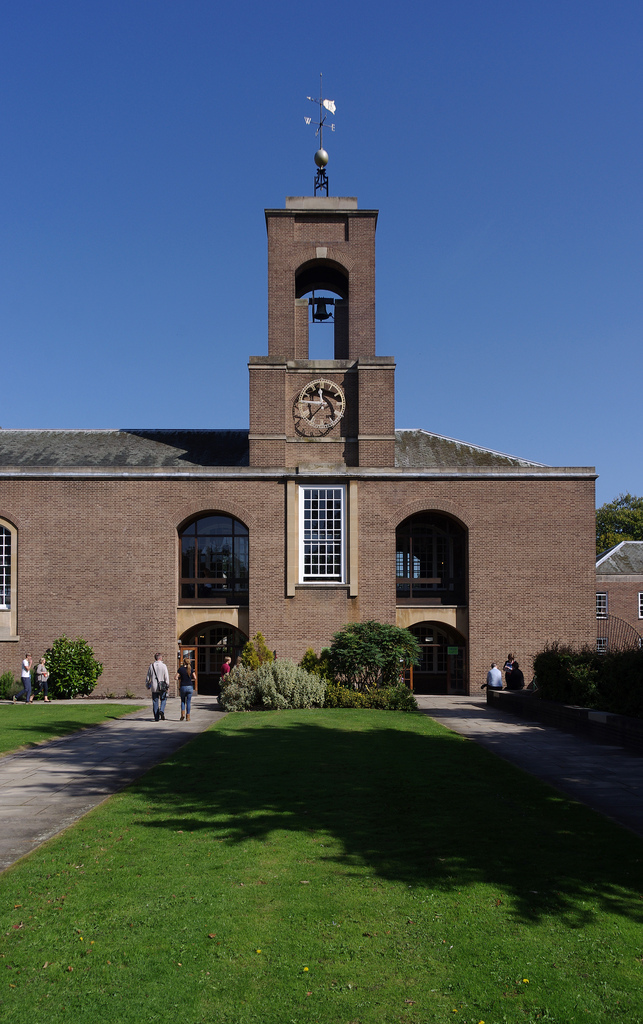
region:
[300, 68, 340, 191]
Weather vane on a clock tower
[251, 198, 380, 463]
old brick clock tower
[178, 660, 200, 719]
woman wearing black shirt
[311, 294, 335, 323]
bell inside the clock tower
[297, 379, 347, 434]
clock on the clock tower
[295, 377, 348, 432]
clock showing eleven forty-five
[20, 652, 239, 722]
people walking into the building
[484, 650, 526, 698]
people sitting outside the building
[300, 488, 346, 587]
window looking into the building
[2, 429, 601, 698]
building attached to the clock tower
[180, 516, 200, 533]
pane on arched window on brick building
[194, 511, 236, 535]
pane on arched window on brick building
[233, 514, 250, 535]
pane on arched window on brick building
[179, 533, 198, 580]
pane on arched window on brick building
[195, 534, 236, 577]
pane on arched window on brick building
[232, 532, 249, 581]
pane on arched window on brick building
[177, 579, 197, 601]
pane on arched window on brick building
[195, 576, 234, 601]
pane on arched window on brick building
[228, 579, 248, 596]
pane on arched window on brick building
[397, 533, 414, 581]
pane on arched window on brick building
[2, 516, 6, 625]
a window on a building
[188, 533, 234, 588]
a window on a building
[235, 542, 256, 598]
a window on a building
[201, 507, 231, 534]
a window on a building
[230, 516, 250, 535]
a window on a building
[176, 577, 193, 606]
a window on a building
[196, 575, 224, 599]
a window on a building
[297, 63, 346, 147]
a metal weather vane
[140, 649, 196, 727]
two people walking on a sidewalk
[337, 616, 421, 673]
a bush with green leaves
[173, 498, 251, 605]
an arched window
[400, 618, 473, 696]
a architectural arch in a building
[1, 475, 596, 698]
the brick facade of a building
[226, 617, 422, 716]
shrubs growing beside a building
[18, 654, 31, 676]
a person wearing a white shirt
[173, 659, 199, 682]
a woman wearing a black shirt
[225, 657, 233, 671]
a person wearing a red shirt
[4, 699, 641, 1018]
the green lawn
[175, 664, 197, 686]
a black shirt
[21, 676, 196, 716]
the denium jeans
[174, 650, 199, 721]
a lady with a ponytail walking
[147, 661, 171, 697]
a black bag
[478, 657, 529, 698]
people sitting on the wall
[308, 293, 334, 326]
a bell at the top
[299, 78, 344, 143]
a compass at the top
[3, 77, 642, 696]
a brick building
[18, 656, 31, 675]
a guy with a white shirt walking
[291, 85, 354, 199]
tall weather vane on top of steeple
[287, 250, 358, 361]
arched belfry with small bell hung in tower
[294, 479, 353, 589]
tall rectangular window with white panes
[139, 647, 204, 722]
man and woman wearing denim walking on sidewalk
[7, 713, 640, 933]
dark shadow of large shade tree on grass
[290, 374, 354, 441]
cream colored clock set at 11:45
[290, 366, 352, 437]
a gold clock on a building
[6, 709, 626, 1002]
grass in between two paths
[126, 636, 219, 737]
two people walking together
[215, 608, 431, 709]
a set of bushes in front of a building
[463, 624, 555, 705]
a group of people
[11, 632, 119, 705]
two people next to a bush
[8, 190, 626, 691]
a large brick building